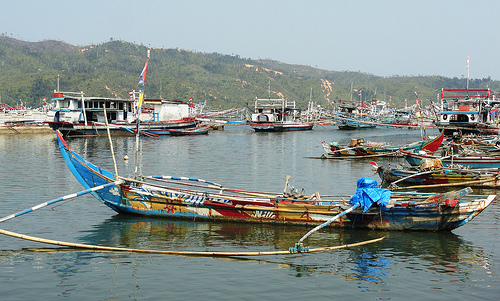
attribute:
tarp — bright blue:
[349, 175, 389, 209]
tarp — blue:
[341, 177, 391, 209]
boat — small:
[55, 125, 498, 229]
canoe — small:
[51, 131, 391, 258]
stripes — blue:
[120, 164, 215, 198]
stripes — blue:
[125, 159, 247, 213]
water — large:
[9, 109, 495, 299]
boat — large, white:
[48, 120, 498, 269]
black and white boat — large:
[430, 87, 497, 141]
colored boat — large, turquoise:
[46, 125, 500, 268]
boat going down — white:
[26, 121, 498, 275]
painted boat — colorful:
[38, 127, 500, 270]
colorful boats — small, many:
[235, 94, 323, 145]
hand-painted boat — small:
[44, 123, 499, 259]